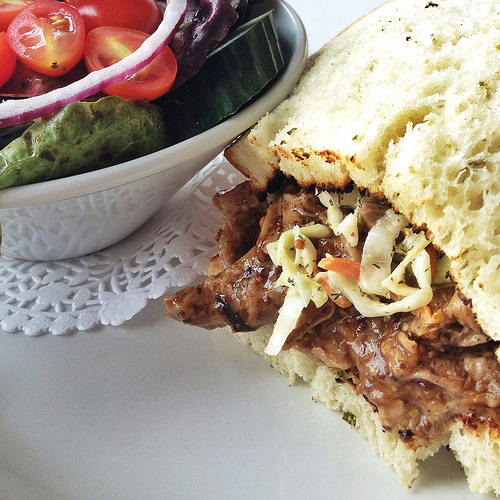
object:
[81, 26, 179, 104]
tomatoes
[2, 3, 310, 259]
bowl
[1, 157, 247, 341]
doily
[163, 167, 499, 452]
meat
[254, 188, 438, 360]
coleslaw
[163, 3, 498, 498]
sandwich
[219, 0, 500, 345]
bread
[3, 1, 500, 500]
surface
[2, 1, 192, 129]
onion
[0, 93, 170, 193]
lettuce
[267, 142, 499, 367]
burnt edge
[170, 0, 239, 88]
cabbage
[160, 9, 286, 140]
cucumber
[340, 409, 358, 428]
seeds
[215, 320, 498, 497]
bread